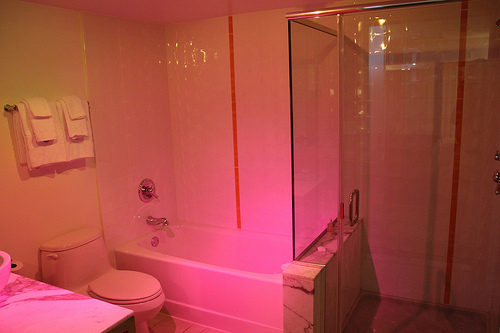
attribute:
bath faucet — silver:
[144, 214, 169, 226]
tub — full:
[111, 216, 284, 331]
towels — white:
[11, 95, 94, 172]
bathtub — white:
[116, 213, 313, 331]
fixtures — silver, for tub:
[133, 179, 170, 249]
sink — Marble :
[7, 258, 125, 330]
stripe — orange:
[436, 3, 472, 303]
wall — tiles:
[166, 7, 340, 238]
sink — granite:
[5, 249, 130, 331]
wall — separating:
[267, 15, 439, 329]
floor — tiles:
[148, 310, 223, 331]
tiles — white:
[149, 68, 246, 130]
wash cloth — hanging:
[22, 97, 53, 117]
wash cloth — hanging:
[59, 94, 86, 119]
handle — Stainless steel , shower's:
[138, 176, 155, 201]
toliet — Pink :
[28, 224, 170, 319]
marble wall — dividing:
[290, 230, 367, 316]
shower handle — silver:
[133, 172, 168, 205]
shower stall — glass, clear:
[284, 1, 499, 331]